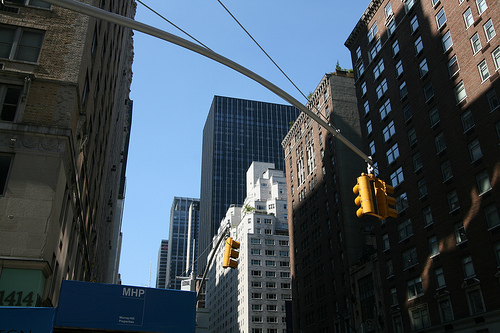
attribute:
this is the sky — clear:
[144, 52, 206, 136]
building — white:
[196, 158, 294, 331]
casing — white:
[197, 164, 290, 330]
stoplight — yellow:
[220, 235, 238, 269]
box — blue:
[56, 280, 197, 330]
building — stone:
[2, 0, 132, 303]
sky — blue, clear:
[115, 3, 373, 287]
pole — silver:
[54, 3, 374, 169]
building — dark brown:
[282, 69, 361, 331]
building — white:
[203, 160, 292, 331]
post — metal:
[306, 94, 366, 171]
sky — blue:
[155, 64, 191, 149]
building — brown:
[212, 91, 412, 307]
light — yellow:
[346, 164, 390, 222]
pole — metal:
[262, 67, 350, 166]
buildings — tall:
[212, 108, 443, 326]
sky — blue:
[149, 58, 193, 139]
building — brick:
[343, 20, 442, 123]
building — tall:
[220, 131, 338, 311]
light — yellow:
[219, 240, 247, 279]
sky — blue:
[143, 89, 189, 177]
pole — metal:
[193, 44, 303, 105]